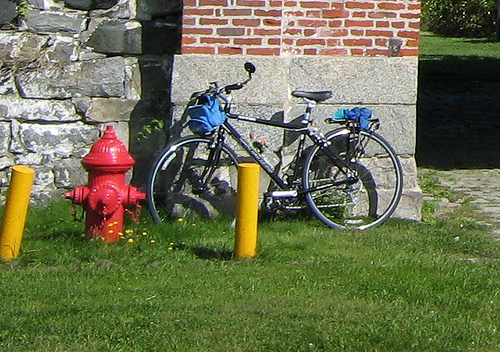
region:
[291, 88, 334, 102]
Black seat on bicycle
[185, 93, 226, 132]
Blue backpack on bicycle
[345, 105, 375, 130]
Blue cloth behind black seat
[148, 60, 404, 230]
Black bicycle leaning against wall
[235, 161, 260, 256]
Yellow pole stuck in green grass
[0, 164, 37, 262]
Yellow pole stuck in green grass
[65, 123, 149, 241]
Red fire hydrant sitting on green grass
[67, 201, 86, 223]
Red chain on fire hydrant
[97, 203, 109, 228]
Red chain on fire hydrant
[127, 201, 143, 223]
Red chain on fire hydrant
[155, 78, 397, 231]
bicycle leaning against building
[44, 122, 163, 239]
red fire hydrant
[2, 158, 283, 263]
two short yellow poles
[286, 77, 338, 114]
black bicycle seat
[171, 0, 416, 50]
red bricks on building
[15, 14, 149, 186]
large stones used to create wall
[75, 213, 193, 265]
small yellow flowers in grass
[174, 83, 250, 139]
small blue bad on front of bike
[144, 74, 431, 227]
bicycle with black frame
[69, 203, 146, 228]
chains on fire hydrant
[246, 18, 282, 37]
WALL MADE OUT OF RED BRICKS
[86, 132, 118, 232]
FIRE HYDRANT IS RED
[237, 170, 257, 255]
YELLOW POLES IN THE GROUND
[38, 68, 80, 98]
WALL MADE OUT OF ROCKS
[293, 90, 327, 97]
BLACK SEAT ON THE BIKE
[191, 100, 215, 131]
BLUE BAG ON THE FRONT OF BIKE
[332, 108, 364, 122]
BLUE ITEM ON THE BACK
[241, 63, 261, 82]
MIRROR ON THE BIKE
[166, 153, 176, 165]
WHITE REFLECTOR ON THE WHEEL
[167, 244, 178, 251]
YELLOW FLOWER IN THE GRASS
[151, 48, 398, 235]
A black bicycle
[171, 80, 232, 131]
A blue lunch bag on front of bicycle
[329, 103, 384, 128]
Blue cloth on back of bicycle seat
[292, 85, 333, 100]
Black bicycle seat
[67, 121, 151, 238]
A red fire hydrant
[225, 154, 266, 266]
A yellow post on right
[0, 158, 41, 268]
A yellow post on left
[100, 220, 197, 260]
Yellow flowers in grass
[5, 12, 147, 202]
White and grey block building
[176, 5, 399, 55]
Red brick building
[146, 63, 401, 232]
a black bicycle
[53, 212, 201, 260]
yellow flowers in the grass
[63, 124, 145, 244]
a red fire hydrant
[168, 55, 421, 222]
gray concrete blocks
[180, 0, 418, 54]
red brick on a building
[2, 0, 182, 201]
a rock wall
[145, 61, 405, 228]
a blue bag hanging on the front of a bicycle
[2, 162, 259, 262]
two metal yellow poles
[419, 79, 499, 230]
a dirt driveway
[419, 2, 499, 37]
green colored shrubs